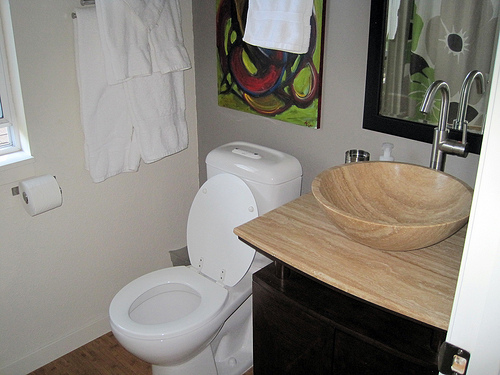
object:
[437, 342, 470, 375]
door latch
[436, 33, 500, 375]
door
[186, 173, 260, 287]
toilet lid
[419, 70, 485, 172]
faucet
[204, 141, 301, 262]
toilet tank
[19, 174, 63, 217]
roll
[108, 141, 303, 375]
toilet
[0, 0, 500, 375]
bathroom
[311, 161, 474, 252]
sink